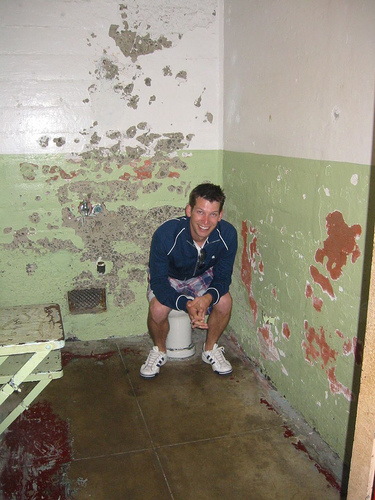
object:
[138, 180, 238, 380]
man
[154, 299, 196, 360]
toilet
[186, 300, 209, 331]
hand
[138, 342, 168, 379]
shoe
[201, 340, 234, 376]
shoe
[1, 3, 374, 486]
wall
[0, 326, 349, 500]
floor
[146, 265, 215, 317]
shorts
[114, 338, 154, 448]
line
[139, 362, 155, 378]
front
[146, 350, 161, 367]
laces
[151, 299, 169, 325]
knee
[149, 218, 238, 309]
jacket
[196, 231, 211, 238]
chin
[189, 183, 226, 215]
hair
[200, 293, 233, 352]
leg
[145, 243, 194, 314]
sleeve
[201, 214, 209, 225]
nose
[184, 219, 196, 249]
collar